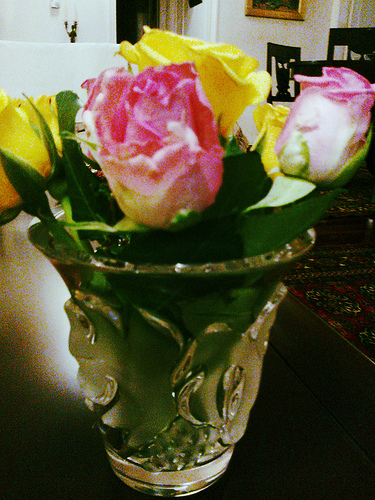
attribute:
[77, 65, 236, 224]
rose — large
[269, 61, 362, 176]
flower — yellow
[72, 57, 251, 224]
flower — yellow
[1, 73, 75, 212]
flower — yellow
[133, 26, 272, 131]
flower — yellow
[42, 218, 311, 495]
vase — large, porcelain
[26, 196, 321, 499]
vase — dark green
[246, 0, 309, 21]
frame — wooden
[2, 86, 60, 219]
rose — yellow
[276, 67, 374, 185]
flowers — pink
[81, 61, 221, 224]
flowers — pink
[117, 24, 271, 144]
flowers — yellow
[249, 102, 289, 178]
flowers — yellow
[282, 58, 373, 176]
rose — white, pink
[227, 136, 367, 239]
leaves — green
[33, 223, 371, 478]
vase — clear, glass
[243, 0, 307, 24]
picture — gold framed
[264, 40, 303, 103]
picture — gold framed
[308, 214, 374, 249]
floor — shiny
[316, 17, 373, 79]
chair — brown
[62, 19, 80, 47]
candle holder — black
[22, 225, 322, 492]
flower pot — large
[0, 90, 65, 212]
flower — yellow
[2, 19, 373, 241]
flowers — yellow, pink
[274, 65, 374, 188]
flower — pink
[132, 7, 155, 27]
doorway — white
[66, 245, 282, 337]
vase — green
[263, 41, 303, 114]
chair — black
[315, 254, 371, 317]
carpet — red, brown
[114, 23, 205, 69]
rose — yellow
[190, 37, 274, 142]
rose — yellow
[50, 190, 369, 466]
table — black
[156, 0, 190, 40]
curtains — colorful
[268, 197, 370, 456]
rug — colorful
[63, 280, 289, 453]
images — raised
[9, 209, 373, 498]
table — black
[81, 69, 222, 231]
rose — pink, yellow